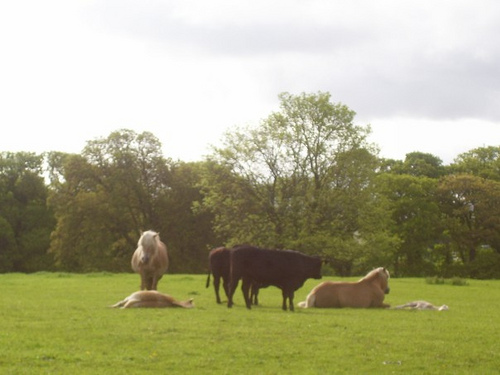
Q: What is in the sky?
A: Clouds.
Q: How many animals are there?
A: Six.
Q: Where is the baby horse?
A: Lying down.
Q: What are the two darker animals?
A: Cows.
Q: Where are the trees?
A: Behind the animals.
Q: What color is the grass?
A: Green.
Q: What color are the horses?
A: Brown.